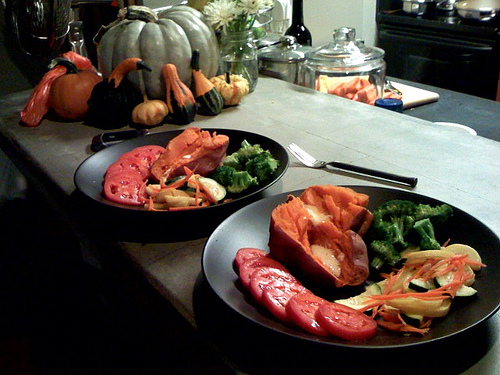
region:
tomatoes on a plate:
[231, 228, 391, 355]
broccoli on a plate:
[365, 184, 452, 267]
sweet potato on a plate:
[269, 183, 369, 292]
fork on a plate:
[283, 133, 421, 187]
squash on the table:
[26, 43, 146, 118]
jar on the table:
[315, 30, 389, 115]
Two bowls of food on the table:
[71, 123, 498, 353]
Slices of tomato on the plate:
[232, 243, 373, 344]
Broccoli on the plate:
[370, 201, 448, 272]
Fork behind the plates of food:
[287, 140, 417, 188]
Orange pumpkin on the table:
[51, 54, 106, 123]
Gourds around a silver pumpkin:
[90, 53, 260, 124]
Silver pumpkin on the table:
[96, 2, 214, 97]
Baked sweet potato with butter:
[271, 182, 372, 286]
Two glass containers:
[260, 25, 387, 105]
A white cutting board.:
[379, 74, 440, 115]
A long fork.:
[288, 139, 418, 185]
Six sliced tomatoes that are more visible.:
[233, 247, 378, 343]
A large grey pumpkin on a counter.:
[97, 4, 222, 99]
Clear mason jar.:
[216, 29, 258, 91]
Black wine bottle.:
[284, 1, 313, 49]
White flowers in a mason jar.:
[203, 0, 273, 27]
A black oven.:
[376, 7, 498, 99]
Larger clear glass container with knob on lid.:
[304, 26, 386, 108]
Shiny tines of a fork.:
[286, 142, 316, 165]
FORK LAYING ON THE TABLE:
[288, 143, 423, 186]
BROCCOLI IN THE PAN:
[416, 218, 434, 249]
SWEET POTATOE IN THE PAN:
[291, 188, 368, 273]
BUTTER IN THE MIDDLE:
[317, 247, 336, 267]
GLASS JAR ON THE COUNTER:
[318, 26, 390, 93]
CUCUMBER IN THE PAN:
[463, 289, 473, 299]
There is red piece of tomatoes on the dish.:
[241, 245, 378, 336]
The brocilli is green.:
[361, 195, 448, 256]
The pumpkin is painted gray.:
[106, 1, 229, 87]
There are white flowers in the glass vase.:
[208, 3, 266, 78]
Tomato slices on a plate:
[233, 233, 375, 339]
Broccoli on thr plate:
[370, 192, 444, 265]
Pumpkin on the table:
[97, 3, 221, 99]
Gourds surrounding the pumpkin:
[21, 46, 246, 131]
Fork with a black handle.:
[283, 132, 419, 187]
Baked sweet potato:
[271, 186, 375, 290]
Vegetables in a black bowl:
[201, 183, 498, 345]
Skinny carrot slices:
[361, 254, 466, 331]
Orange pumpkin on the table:
[48, 50, 100, 125]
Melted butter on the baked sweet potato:
[313, 238, 343, 275]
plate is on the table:
[201, 182, 498, 352]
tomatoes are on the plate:
[232, 247, 379, 341]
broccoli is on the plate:
[374, 200, 456, 270]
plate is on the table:
[71, 125, 291, 214]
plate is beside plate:
[71, 126, 291, 211]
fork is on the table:
[286, 142, 422, 187]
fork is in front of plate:
[288, 140, 419, 186]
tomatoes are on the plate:
[101, 144, 163, 208]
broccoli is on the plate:
[215, 137, 280, 194]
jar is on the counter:
[304, 27, 391, 106]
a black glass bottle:
[286, 3, 315, 43]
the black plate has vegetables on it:
[214, 183, 499, 343]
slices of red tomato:
[222, 252, 377, 338]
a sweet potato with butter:
[285, 185, 374, 280]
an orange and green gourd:
[192, 53, 223, 115]